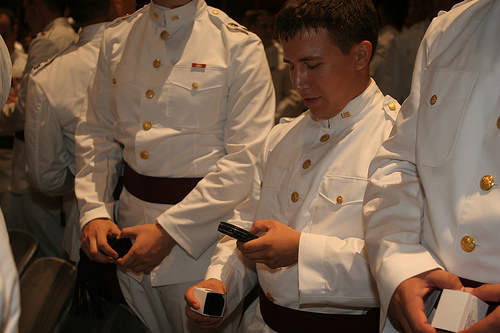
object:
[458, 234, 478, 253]
button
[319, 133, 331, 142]
button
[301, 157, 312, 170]
button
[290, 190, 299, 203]
button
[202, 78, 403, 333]
shirt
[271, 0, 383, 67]
hair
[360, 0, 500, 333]
shirt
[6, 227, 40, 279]
chair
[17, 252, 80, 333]
chair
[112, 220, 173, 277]
hand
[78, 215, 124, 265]
hand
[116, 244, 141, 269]
finger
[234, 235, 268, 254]
finger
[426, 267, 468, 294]
finger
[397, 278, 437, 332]
finger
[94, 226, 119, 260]
finger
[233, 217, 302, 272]
hand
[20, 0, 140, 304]
man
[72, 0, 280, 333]
man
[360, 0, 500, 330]
man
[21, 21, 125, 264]
uniform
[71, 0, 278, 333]
uniform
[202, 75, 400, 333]
uniform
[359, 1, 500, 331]
uniform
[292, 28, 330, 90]
sweat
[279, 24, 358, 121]
face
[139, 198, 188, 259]
waist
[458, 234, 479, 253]
buttons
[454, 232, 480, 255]
shiny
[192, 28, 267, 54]
shoulder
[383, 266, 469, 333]
hands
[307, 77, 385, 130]
collar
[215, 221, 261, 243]
cell phone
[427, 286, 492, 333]
box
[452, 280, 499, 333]
hands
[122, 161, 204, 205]
wide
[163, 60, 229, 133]
pocket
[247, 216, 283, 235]
thumb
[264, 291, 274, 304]
button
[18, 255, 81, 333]
back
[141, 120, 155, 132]
gold buttons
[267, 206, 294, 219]
white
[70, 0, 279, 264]
shirt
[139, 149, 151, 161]
buttons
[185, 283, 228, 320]
box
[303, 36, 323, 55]
shine